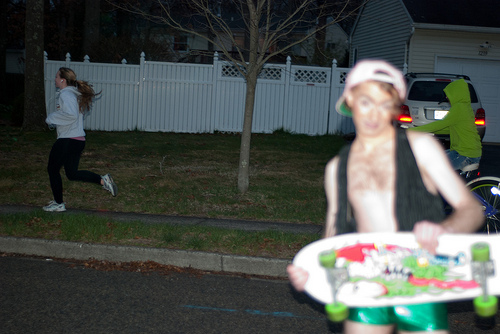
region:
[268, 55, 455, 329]
a boy holding a skateboard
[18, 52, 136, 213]
a woman running on a sidewalk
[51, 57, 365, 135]
a white plastic fence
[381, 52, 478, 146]
a white car parked in a driveway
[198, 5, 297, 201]
a small tree with no leaves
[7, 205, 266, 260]
a patch of green grass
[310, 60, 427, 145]
a boy wearing a hat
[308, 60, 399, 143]
a boy wearing a hat backwards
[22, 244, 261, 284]
leaves on the ground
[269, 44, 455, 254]
a boy wearing a vest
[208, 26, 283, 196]
A tree without leaves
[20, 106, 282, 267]
A grey sidewalk on a lawn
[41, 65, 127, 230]
A runner in white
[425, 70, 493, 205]
A biker with a yellow sweatshirt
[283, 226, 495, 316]
A white skateboard with yellow wheels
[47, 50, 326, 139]
Tall, white fence with boards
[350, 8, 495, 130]
A yellow house with a white garage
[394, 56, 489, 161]
A white SUV sits on the driveway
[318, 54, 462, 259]
A boy with a pink hat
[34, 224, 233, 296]
Brown leaves in the gutter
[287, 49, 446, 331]
man with hair chest, black vest and pink cap holding a skateboard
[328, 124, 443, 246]
black vest that the man carrying the skateboard is wearing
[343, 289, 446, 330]
bright green shorts that the man with the skateboard is wearing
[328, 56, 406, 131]
pink cap the man with the skateboard is wearing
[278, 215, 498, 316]
skateboard that the man in the pink cap, black vest and green shorts is carrying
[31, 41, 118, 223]
woman with dark blond hair, white jacket and black pants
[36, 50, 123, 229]
woman jogging down the sidewalk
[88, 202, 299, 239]
sidewalk with woman jogging and child riding bicycle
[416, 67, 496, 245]
child in green hoodie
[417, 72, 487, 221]
child riding bicycle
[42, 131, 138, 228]
The woman is wearing pants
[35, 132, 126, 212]
The woman is wearing black pants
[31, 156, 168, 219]
The woman is wearing shoes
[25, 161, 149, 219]
The woman is wearing white shoes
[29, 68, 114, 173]
The woman is wearing a jacket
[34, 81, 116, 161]
The woman is wearing a white jacket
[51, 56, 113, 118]
The woman has hair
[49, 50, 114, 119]
The woman has long hair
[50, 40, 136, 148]
The woman has brown hair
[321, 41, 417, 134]
The man is wearing a hat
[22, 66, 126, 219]
a girl jogging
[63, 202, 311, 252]
the sidewalk is concrete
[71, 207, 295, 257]
the grass is green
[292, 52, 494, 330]
the boy has a skate board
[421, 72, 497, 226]
a person riding a bike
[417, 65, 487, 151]
the hoodie is green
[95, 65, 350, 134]
the fence is white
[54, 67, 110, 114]
her hair is long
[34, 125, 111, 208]
she is wearing black pants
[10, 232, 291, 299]
the curb is by the road